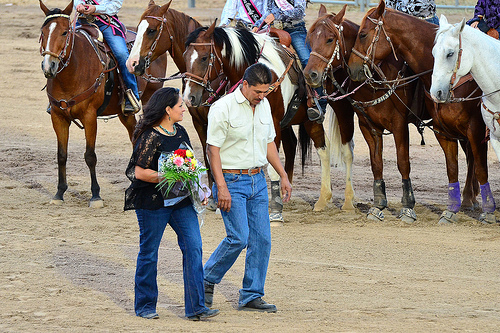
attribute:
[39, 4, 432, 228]
horse — brown, standing, white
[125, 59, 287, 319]
people — walking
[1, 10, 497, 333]
ground — dirt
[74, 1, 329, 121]
person — sitting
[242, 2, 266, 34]
sash — black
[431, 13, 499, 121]
horse — white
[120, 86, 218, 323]
woman — walking, carrying, wearing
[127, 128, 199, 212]
top — black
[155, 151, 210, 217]
flower — colorful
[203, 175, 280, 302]
jean — blue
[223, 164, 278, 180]
belt — brown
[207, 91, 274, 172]
shirt — white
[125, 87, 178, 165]
hair — black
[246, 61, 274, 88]
hair — dark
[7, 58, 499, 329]
sand — brown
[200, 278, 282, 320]
shoe — black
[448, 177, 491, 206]
cloth — purple